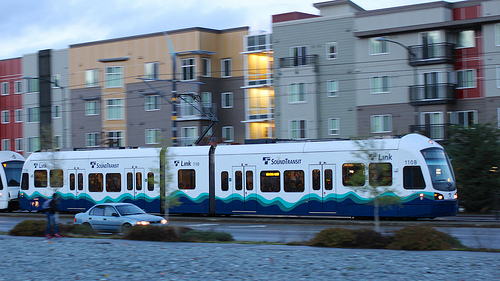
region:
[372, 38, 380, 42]
A street lamp high up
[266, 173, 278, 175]
Light shining in the train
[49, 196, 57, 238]
A person standing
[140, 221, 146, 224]
The shining light of a car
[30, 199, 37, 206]
Reflection on the side of the train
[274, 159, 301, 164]
Writing on the train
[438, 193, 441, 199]
The front light of the train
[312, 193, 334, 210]
The closed doors of the train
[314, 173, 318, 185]
A window on the train door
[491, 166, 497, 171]
Reflection of light in the bushes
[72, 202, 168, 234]
the car on the road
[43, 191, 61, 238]
the person walking alone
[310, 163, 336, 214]
the doors on the train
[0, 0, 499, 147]
the building behind the train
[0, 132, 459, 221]
the train on the track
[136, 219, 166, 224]
the lights on the car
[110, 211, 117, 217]
the mirror on the car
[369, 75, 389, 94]
the window on the building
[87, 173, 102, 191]
the window on the train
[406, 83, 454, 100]
the railing on the balcony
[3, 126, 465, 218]
Train on the tracks.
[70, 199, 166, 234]
Car on the road.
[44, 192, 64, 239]
Person standing on the ground.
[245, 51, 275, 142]
Lights in the building.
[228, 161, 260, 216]
Door on the train.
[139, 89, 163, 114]
Window in the building.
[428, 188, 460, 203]
Headlight on train.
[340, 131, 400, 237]
Tree in the forefront.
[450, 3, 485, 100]
Red coloring on the building.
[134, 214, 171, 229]
Head lights on the car.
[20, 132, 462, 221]
white and green train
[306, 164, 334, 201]
passenger door on right side of the train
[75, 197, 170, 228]
car on the side of the train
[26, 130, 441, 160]
top of the train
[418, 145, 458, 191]
windshield of the train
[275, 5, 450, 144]
gray building on the side of the train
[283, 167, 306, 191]
passenger window on the right side of the train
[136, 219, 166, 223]
headlights on the front of the car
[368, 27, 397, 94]
windows in the gray building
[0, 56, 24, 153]
red colored building